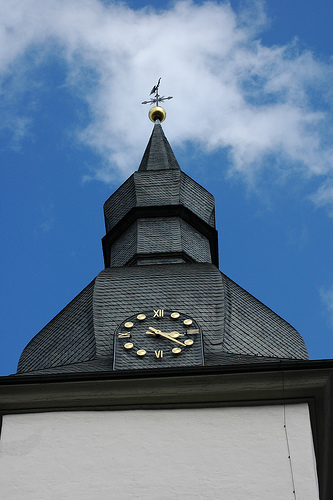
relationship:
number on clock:
[184, 336, 194, 348] [112, 305, 202, 366]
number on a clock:
[116, 324, 135, 345] [94, 291, 244, 388]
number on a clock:
[153, 306, 166, 318] [111, 307, 209, 360]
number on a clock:
[137, 312, 146, 319] [117, 306, 199, 359]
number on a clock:
[171, 346, 180, 355] [113, 302, 205, 385]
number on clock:
[154, 349, 166, 359] [112, 305, 202, 366]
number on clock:
[189, 328, 203, 342] [112, 305, 202, 366]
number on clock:
[153, 306, 166, 318] [104, 297, 210, 377]